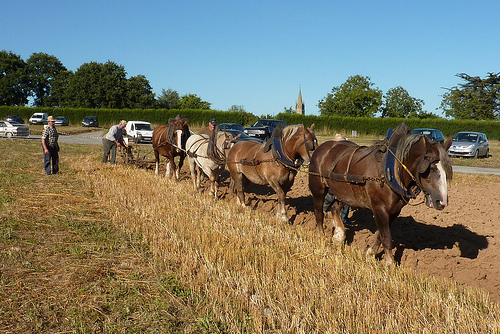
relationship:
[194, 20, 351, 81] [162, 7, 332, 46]
cloud in sky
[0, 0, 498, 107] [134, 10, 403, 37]
cloud in sky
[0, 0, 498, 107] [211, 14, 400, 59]
cloud in sky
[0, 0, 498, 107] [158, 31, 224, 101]
cloud are in sky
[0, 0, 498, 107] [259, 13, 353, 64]
cloud are in sky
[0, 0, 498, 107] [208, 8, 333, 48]
cloud are in sky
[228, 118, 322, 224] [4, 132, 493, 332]
brown horse in field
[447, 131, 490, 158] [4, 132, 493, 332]
car parked in field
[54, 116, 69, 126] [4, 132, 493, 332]
car parked in field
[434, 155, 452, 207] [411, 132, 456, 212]
marking on face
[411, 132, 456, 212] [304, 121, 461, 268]
face on horse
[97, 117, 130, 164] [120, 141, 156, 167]
man directing plow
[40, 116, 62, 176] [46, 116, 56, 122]
man wearing cap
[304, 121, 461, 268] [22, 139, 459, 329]
horse in field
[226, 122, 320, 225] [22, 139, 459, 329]
brown horse in field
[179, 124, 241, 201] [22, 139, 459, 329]
horse in field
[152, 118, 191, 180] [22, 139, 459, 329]
brown horse in field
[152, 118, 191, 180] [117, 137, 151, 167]
brown horse pulling plow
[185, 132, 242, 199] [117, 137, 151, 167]
horse pulling plow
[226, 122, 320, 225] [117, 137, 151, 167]
brown horse pulling plow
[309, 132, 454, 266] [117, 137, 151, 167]
horse pulling plow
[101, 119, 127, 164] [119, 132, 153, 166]
man standing by plow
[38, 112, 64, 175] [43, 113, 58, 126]
man wearing cap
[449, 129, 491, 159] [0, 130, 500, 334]
car parked on field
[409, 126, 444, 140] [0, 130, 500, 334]
car parked on field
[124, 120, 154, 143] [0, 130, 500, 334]
car parked on field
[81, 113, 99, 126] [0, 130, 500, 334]
car parked on field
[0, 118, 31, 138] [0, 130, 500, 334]
car parked on field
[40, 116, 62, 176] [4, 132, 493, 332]
man in field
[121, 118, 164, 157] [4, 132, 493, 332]
car parked in field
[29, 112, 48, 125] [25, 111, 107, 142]
car parked in field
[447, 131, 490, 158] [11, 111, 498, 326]
car parked field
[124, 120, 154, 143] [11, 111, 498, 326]
car parked field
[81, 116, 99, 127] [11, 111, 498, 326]
car parked field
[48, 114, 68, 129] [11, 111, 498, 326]
car parked field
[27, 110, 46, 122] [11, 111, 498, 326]
car parked field